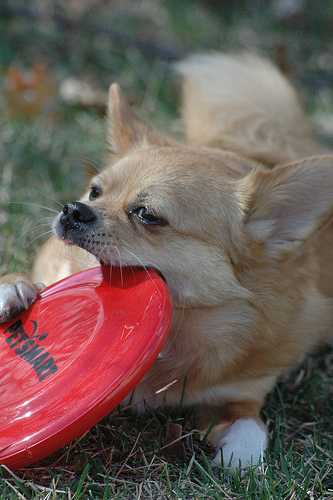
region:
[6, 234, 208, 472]
a dog has a disk in its mouth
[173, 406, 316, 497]
The dog has a white paw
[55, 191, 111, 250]
The dog has a wet nose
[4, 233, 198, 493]
the frisbee is from a pet store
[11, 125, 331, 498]
The dog is laying on the grass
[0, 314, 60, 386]
black writing on red frisbee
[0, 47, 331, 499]
dog chewing on red frisbee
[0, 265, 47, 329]
one dog paw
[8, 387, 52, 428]
white light reflected on red frisbee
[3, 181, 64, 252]
white dog whiskers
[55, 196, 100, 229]
one dog nose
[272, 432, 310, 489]
green blades of grass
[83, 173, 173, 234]
two dog eyes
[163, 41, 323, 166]
one tan dog tail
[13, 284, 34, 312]
one dog paw nail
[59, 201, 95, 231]
Shiny black dog nose.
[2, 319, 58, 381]
Black word PETSMART.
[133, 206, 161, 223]
A dogs left eye.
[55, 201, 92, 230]
A black dog nose.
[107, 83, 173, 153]
A dog's right brown ear.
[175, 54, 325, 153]
A dog's puffy brown tail.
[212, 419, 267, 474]
The end of a dog's white left paw.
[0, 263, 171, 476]
A red frisbee.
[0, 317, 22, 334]
A black P on a frisbee.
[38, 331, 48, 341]
A black circle on a red frisbee.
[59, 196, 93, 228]
A wet black dog nose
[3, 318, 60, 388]
A black Petsmart logo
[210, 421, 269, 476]
A white furry dog paw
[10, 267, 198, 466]
A red Frisbee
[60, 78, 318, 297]
A small brown dog's head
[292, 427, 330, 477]
Some blades of brownish green grass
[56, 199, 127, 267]
A doggie snout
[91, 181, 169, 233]
Two small doggie eyes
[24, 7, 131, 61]
Blurry indistinct background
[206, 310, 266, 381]
A patch of brown and white dog fur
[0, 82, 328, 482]
dog with frisbee in mouth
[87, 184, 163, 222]
two eyes of dog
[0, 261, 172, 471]
red frisbee with logo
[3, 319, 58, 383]
black logo on red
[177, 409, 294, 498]
dog paw behind blades of grass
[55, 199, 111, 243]
black nose on snout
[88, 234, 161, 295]
whiskers on dog cheek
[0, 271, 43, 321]
claws on dog foot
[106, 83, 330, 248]
pointed ears on head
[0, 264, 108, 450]
light reflection on frisbee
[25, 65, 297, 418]
this is a dog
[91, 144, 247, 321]
the dog is blonde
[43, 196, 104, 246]
the nose is black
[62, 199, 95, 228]
A black dog nose.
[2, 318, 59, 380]
The black word PETSMART on a frisbee.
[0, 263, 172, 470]
A red frisbee with PETSMART on the top.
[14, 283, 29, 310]
A clear dog claw.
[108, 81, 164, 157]
A dogs right brown ear.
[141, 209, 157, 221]
A dogs left black eye.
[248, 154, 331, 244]
A dogs left brown ear.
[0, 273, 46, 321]
A dogs paw on a frisbee.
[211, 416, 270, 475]
A dogs white paw top.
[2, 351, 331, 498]
A green grassy area.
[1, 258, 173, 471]
red frisbee in a dog's mouth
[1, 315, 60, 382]
black logo on a frisbee